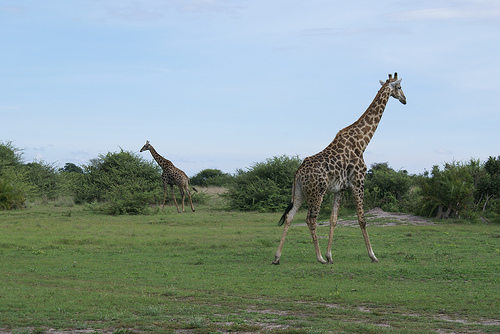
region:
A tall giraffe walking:
[278, 72, 405, 265]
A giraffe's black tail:
[273, 196, 293, 225]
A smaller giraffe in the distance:
[141, 140, 201, 211]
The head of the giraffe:
[377, 70, 408, 104]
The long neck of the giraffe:
[346, 91, 385, 153]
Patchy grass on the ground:
[0, 210, 499, 332]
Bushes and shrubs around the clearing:
[0, 147, 496, 224]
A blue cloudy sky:
[2, 1, 496, 157]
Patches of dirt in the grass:
[330, 201, 425, 227]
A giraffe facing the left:
[140, 142, 193, 203]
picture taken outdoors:
[20, 31, 465, 331]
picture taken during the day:
[17, 18, 485, 330]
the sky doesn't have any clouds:
[35, 19, 370, 109]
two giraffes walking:
[90, 58, 467, 330]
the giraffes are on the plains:
[105, 60, 465, 298]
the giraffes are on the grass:
[80, 35, 442, 305]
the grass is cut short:
[111, 260, 229, 294]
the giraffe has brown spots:
[300, 32, 417, 242]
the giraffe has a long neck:
[347, 65, 407, 145]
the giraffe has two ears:
[377, 66, 414, 110]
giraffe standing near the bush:
[135, 124, 203, 219]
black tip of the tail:
[265, 195, 292, 227]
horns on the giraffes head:
[382, 70, 398, 82]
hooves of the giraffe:
[267, 250, 382, 265]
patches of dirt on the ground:
[369, 205, 434, 224]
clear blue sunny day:
[192, 50, 298, 102]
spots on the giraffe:
[322, 155, 339, 170]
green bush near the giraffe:
[90, 163, 152, 217]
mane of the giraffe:
[371, 96, 379, 101]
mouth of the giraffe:
[398, 94, 406, 106]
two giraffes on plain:
[135, 124, 438, 274]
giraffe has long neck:
[292, 109, 404, 278]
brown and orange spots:
[288, 82, 373, 229]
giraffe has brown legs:
[295, 186, 403, 269]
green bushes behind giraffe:
[262, 159, 499, 247]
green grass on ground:
[90, 239, 479, 326]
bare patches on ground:
[163, 277, 489, 332]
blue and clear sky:
[163, 16, 254, 137]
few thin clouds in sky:
[390, 41, 478, 120]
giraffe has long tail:
[272, 154, 334, 236]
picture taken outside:
[10, 11, 498, 319]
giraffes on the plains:
[92, 40, 458, 326]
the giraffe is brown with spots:
[237, 35, 429, 307]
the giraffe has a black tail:
[275, 187, 293, 222]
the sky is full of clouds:
[59, 15, 351, 80]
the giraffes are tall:
[122, 55, 456, 257]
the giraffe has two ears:
[376, 55, 403, 100]